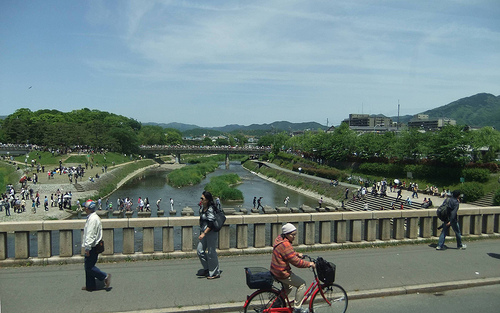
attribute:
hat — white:
[281, 222, 298, 236]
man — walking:
[80, 199, 112, 292]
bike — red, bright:
[243, 259, 350, 313]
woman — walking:
[192, 190, 229, 281]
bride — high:
[0, 219, 499, 307]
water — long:
[109, 161, 312, 212]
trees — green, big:
[3, 105, 145, 157]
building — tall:
[349, 111, 396, 135]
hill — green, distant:
[425, 88, 497, 130]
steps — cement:
[349, 187, 422, 215]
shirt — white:
[84, 214, 105, 249]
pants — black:
[84, 244, 109, 294]